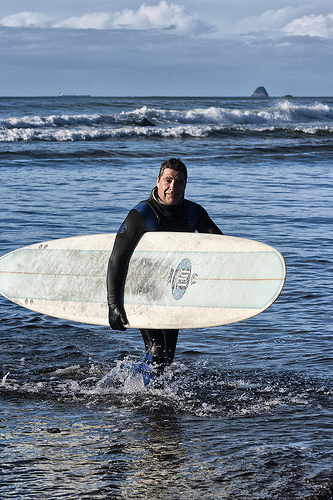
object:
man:
[106, 155, 225, 379]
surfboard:
[0, 231, 286, 329]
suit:
[106, 185, 224, 372]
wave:
[1, 100, 333, 144]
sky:
[1, 0, 333, 69]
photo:
[1, 0, 331, 498]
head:
[155, 158, 188, 205]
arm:
[106, 199, 147, 331]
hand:
[108, 299, 130, 331]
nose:
[169, 180, 176, 192]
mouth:
[167, 192, 178, 199]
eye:
[165, 178, 173, 183]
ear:
[155, 173, 159, 186]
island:
[251, 85, 270, 98]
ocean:
[1, 95, 333, 499]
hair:
[164, 158, 184, 170]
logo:
[171, 258, 191, 301]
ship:
[280, 93, 294, 99]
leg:
[139, 328, 166, 368]